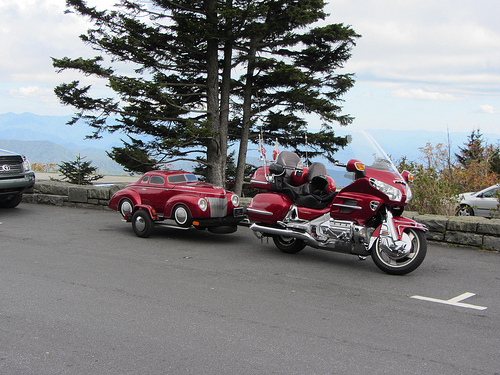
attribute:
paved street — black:
[0, 200, 499, 373]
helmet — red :
[302, 170, 345, 207]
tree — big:
[53, 0, 408, 187]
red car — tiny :
[107, 168, 244, 230]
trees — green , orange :
[400, 146, 482, 217]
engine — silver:
[309, 217, 364, 239]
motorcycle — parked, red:
[245, 129, 429, 275]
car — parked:
[435, 173, 492, 212]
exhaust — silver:
[254, 222, 314, 242]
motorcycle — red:
[253, 143, 429, 271]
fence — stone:
[438, 198, 489, 246]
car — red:
[107, 169, 243, 244]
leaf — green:
[65, 117, 79, 126]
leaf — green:
[85, 134, 93, 141]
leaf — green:
[95, 54, 105, 61]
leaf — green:
[133, 67, 145, 73]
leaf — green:
[114, 117, 125, 123]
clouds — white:
[1, 1, 498, 133]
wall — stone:
[12, 174, 496, 251]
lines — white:
[399, 282, 493, 340]